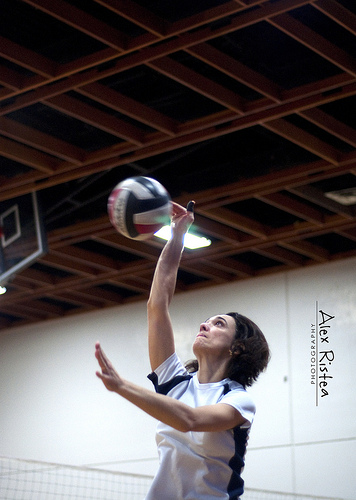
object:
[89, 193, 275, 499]
person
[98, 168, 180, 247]
ball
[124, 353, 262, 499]
uniform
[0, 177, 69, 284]
hoop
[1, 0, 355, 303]
ceiling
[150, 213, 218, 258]
light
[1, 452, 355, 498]
net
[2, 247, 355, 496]
wall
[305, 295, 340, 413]
logo